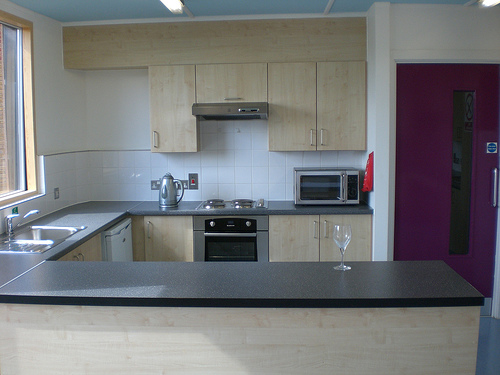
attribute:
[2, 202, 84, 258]
fixtures — silver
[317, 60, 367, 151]
cabinet — wood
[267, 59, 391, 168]
cupboard — brown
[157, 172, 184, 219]
kettle — tall, silver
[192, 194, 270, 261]
stove — electric, in a room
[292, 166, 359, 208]
silver microwave — black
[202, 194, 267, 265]
stove — silver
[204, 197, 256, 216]
burners — four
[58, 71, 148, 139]
wall — white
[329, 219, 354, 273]
glass — empty, wine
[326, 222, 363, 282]
glass — shiny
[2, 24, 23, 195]
window — closed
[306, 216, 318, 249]
handle — metal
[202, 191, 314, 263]
stove — silver, black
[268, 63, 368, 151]
cupboard — wooden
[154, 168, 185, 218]
pitcher — thermos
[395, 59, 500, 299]
door — purple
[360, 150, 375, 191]
mitten — red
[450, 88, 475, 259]
window — long, glass